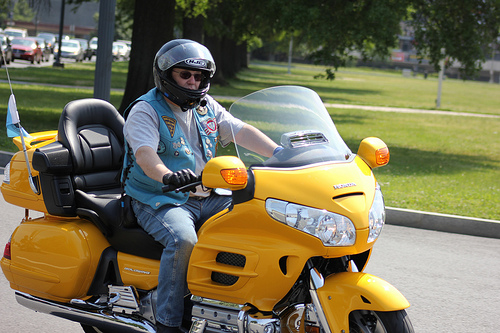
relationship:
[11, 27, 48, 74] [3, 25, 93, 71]
car on street